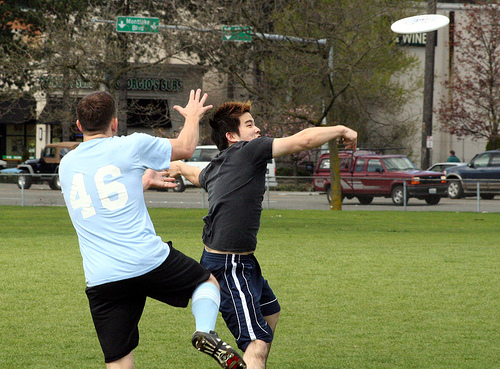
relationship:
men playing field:
[50, 80, 367, 367] [322, 291, 425, 368]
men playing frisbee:
[50, 80, 367, 367] [93, 0, 500, 243]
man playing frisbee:
[55, 83, 252, 367] [389, 11, 453, 37]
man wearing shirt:
[156, 97, 366, 368] [161, 86, 330, 267]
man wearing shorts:
[156, 97, 366, 368] [194, 245, 285, 350]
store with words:
[102, 62, 209, 167] [34, 69, 188, 99]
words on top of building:
[34, 69, 188, 99] [22, 64, 210, 165]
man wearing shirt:
[55, 83, 252, 367] [57, 129, 177, 292]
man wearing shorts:
[55, 83, 252, 367] [77, 236, 216, 365]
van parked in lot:
[167, 142, 273, 197] [262, 152, 498, 209]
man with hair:
[156, 97, 366, 368] [205, 97, 248, 156]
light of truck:
[440, 176, 446, 184] [314, 150, 454, 207]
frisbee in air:
[389, 12, 449, 34] [60, 7, 467, 67]